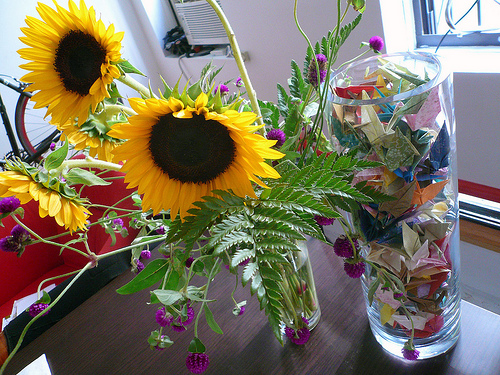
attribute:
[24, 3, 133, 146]
sunflower — yellow, to the left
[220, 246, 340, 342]
vase — clear, glass, to the left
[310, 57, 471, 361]
vase — to the right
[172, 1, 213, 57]
air conditioner — white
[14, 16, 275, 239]
sunflowers — yellow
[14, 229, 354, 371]
table — brown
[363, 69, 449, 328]
origami — green, orange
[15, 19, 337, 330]
flowers — black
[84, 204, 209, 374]
flowers — purple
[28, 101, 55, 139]
spokes — metal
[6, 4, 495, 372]
image — daytime, indoor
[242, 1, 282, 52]
wall — clean, white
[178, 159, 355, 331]
leaves — green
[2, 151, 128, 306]
couch — red